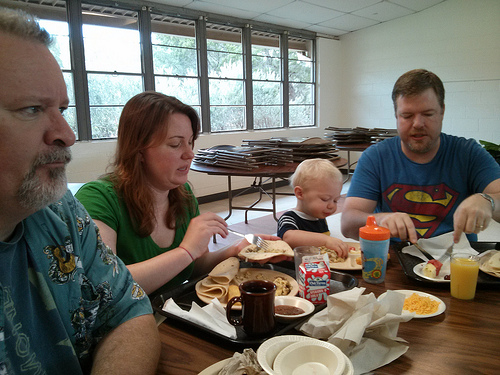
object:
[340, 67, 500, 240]
man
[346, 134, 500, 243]
superman shirt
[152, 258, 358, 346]
tray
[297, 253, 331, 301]
milk carton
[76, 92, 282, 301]
woman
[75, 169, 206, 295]
green shirt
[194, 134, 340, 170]
chairs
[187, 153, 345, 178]
table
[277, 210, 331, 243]
boy's shirt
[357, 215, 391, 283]
sippy cup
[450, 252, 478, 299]
cup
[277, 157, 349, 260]
baby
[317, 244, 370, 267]
food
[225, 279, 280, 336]
coffee mug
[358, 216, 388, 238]
sippy cup lid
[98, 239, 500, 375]
table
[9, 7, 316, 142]
windows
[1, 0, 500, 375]
room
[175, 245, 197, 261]
bracelet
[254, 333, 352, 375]
plate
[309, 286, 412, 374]
napkins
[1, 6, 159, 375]
man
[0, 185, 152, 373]
blue shirt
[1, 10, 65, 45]
mans hair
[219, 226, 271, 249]
fork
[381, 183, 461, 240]
logo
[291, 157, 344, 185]
boys hair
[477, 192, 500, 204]
watch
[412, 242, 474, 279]
food